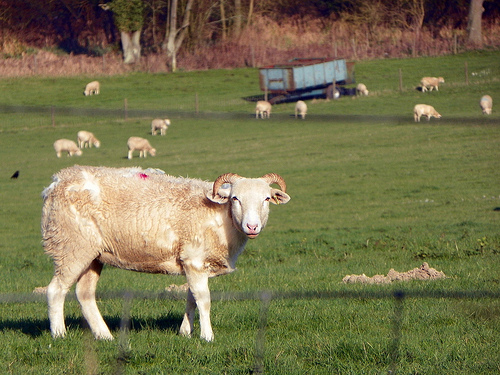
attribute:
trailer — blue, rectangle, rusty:
[257, 55, 359, 105]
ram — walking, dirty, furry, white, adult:
[41, 164, 291, 341]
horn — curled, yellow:
[260, 171, 286, 193]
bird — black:
[12, 168, 23, 178]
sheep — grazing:
[413, 103, 441, 124]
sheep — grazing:
[125, 135, 159, 162]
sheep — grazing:
[53, 139, 82, 157]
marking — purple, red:
[138, 171, 152, 180]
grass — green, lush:
[1, 46, 500, 373]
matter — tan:
[341, 261, 447, 284]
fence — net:
[1, 58, 497, 131]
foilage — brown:
[2, 0, 498, 79]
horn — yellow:
[211, 170, 235, 199]